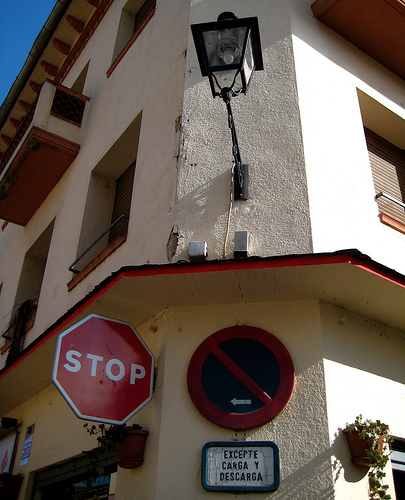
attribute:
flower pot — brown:
[342, 428, 390, 475]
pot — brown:
[339, 426, 384, 466]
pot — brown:
[111, 425, 149, 469]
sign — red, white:
[13, 288, 162, 415]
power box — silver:
[229, 229, 263, 253]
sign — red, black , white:
[186, 324, 293, 431]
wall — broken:
[174, 173, 212, 224]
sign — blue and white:
[192, 437, 286, 493]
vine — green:
[343, 413, 395, 498]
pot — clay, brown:
[116, 419, 147, 472]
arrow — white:
[228, 395, 251, 408]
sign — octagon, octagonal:
[51, 312, 155, 425]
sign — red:
[175, 19, 260, 135]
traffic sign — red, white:
[50, 312, 158, 434]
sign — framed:
[198, 434, 283, 498]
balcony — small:
[61, 166, 163, 288]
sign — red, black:
[191, 319, 283, 444]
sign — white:
[198, 441, 281, 493]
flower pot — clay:
[343, 425, 387, 469]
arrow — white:
[226, 395, 256, 408]